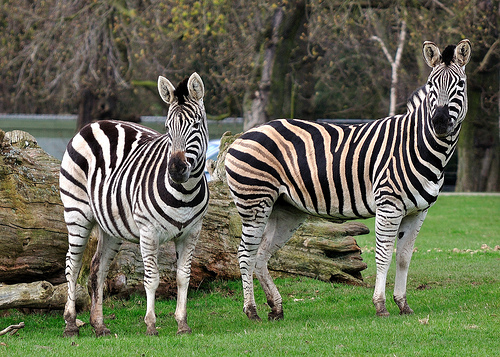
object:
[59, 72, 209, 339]
zebra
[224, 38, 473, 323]
zebra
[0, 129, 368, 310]
tree trunk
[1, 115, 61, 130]
water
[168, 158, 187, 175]
nose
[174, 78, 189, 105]
hair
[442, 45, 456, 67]
hair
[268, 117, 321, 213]
stripe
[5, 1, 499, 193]
forest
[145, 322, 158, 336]
hoof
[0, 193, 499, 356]
grass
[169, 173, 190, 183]
mouth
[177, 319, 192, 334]
hoof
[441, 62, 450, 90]
fur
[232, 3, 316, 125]
tree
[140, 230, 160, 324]
limb